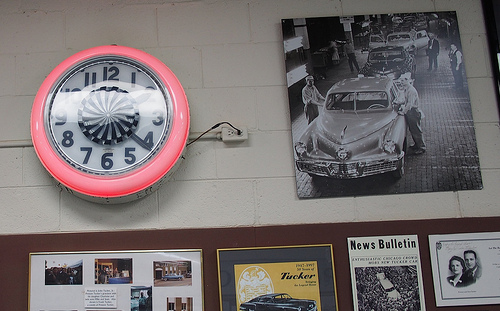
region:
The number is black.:
[96, 60, 120, 87]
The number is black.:
[78, 68, 99, 89]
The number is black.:
[58, 128, 75, 149]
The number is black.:
[77, 141, 96, 169]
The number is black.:
[96, 145, 117, 173]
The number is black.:
[120, 141, 139, 168]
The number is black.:
[145, 105, 168, 127]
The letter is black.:
[346, 234, 358, 251]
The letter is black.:
[374, 236, 386, 252]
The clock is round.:
[18, 33, 203, 212]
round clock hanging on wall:
[28, 44, 190, 200]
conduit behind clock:
[2, 138, 32, 153]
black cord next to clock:
[181, 121, 243, 151]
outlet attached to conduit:
[221, 124, 248, 142]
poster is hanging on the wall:
[278, 10, 486, 197]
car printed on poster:
[293, 75, 408, 180]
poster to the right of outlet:
[280, 9, 485, 198]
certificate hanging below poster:
[428, 229, 499, 304]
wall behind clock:
[1, 1, 498, 232]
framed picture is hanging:
[215, 243, 340, 309]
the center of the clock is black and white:
[75, 85, 139, 143]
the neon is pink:
[28, 42, 189, 194]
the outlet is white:
[218, 125, 247, 143]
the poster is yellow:
[236, 261, 316, 309]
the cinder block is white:
[160, 178, 255, 228]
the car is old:
[295, 73, 410, 178]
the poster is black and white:
[278, 12, 485, 199]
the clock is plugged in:
[185, 122, 248, 139]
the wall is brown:
[2, 213, 499, 308]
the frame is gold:
[216, 240, 339, 307]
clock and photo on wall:
[5, 20, 499, 247]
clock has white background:
[16, 23, 207, 208]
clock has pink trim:
[11, 39, 196, 206]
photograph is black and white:
[258, 5, 491, 216]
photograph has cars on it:
[273, 6, 488, 193]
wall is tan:
[160, 0, 289, 105]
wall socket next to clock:
[188, 99, 277, 186]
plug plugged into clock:
[177, 94, 268, 170]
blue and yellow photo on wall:
[191, 229, 351, 309]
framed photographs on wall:
[3, 240, 219, 308]